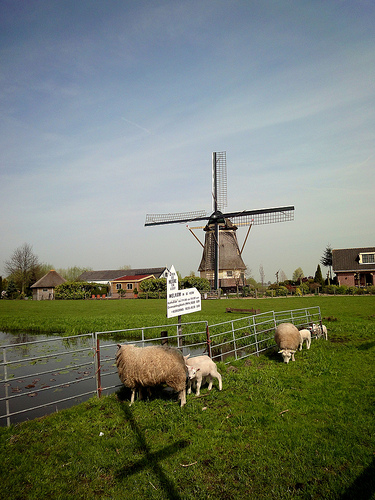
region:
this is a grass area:
[40, 422, 142, 485]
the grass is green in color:
[232, 429, 308, 459]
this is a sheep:
[100, 339, 181, 389]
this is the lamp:
[197, 358, 220, 383]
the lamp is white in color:
[201, 363, 212, 374]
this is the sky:
[85, 11, 275, 118]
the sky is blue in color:
[112, 17, 212, 100]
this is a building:
[334, 241, 374, 271]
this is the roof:
[334, 249, 349, 263]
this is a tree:
[9, 246, 31, 294]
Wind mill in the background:
[139, 145, 297, 292]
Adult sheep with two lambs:
[113, 341, 226, 410]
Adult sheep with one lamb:
[273, 318, 313, 364]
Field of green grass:
[0, 298, 373, 499]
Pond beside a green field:
[0, 313, 255, 432]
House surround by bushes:
[321, 245, 374, 295]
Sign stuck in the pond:
[161, 261, 203, 348]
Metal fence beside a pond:
[0, 302, 324, 430]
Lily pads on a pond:
[3, 334, 95, 385]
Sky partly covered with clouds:
[1, 0, 374, 278]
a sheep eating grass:
[116, 316, 330, 404]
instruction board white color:
[164, 261, 205, 314]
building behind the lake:
[42, 264, 177, 302]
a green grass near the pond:
[152, 425, 356, 475]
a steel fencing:
[11, 347, 89, 398]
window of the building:
[112, 283, 135, 289]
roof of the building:
[339, 251, 359, 272]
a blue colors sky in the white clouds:
[70, 41, 333, 126]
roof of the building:
[338, 254, 349, 270]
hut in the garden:
[36, 269, 70, 304]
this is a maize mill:
[192, 208, 260, 283]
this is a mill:
[207, 150, 231, 208]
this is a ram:
[118, 341, 184, 396]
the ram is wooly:
[130, 349, 174, 381]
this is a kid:
[185, 351, 216, 389]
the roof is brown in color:
[219, 235, 234, 265]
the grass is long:
[251, 388, 343, 478]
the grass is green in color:
[237, 373, 352, 467]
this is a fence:
[57, 330, 101, 393]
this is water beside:
[42, 336, 75, 365]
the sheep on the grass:
[116, 338, 233, 398]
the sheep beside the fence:
[111, 316, 353, 384]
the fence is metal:
[1, 294, 337, 407]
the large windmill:
[140, 143, 281, 279]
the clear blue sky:
[35, 87, 55, 110]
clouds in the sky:
[70, 120, 119, 180]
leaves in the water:
[15, 360, 54, 390]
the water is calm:
[33, 341, 63, 396]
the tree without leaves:
[6, 245, 36, 293]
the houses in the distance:
[49, 265, 173, 307]